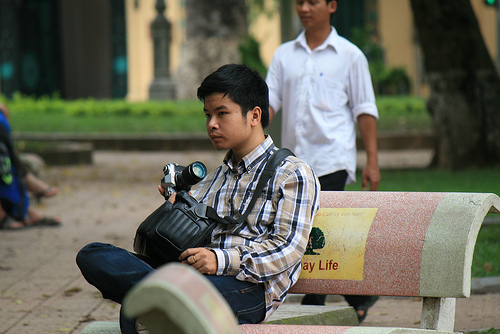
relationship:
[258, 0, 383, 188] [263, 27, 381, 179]
man wears shirt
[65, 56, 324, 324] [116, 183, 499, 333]
man on bench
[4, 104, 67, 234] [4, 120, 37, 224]
woman wears dress